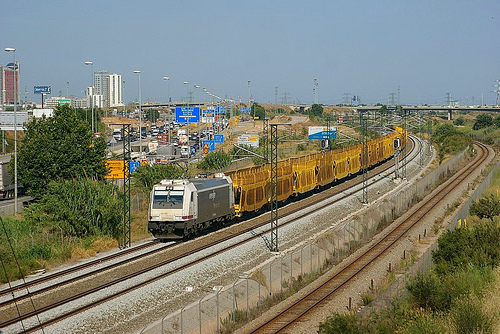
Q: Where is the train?
A: On the tracks.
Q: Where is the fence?
A: Around the tracks.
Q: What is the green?
A: Trees.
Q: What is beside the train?
A: Roads.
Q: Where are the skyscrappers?
A: The background.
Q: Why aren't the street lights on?
A: It's daytime.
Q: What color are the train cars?
A: Gold.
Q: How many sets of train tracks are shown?
A: 3.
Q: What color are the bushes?
A: Green.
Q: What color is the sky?
A: Blue.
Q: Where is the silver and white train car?
A: In front.